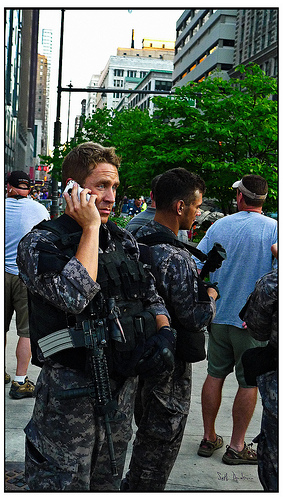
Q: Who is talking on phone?
A: Man.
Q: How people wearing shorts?
A: 2.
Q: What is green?
A: Trees.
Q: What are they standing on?
A: Cement.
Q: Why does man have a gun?
A: Army.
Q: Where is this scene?
A: On a sidewalk.